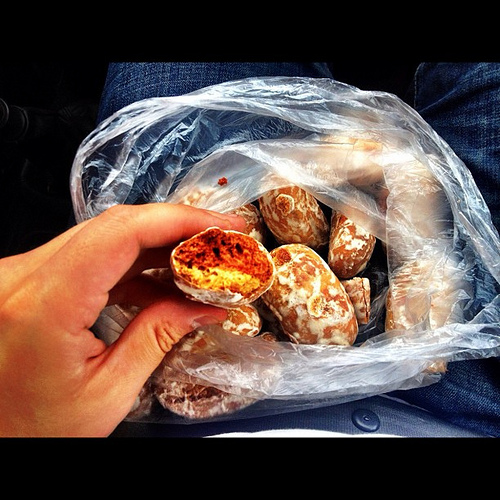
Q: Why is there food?
A: Eating.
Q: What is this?
A: Food.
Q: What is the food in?
A: Pack.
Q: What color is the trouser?
A: Blue.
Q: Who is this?
A: Person.